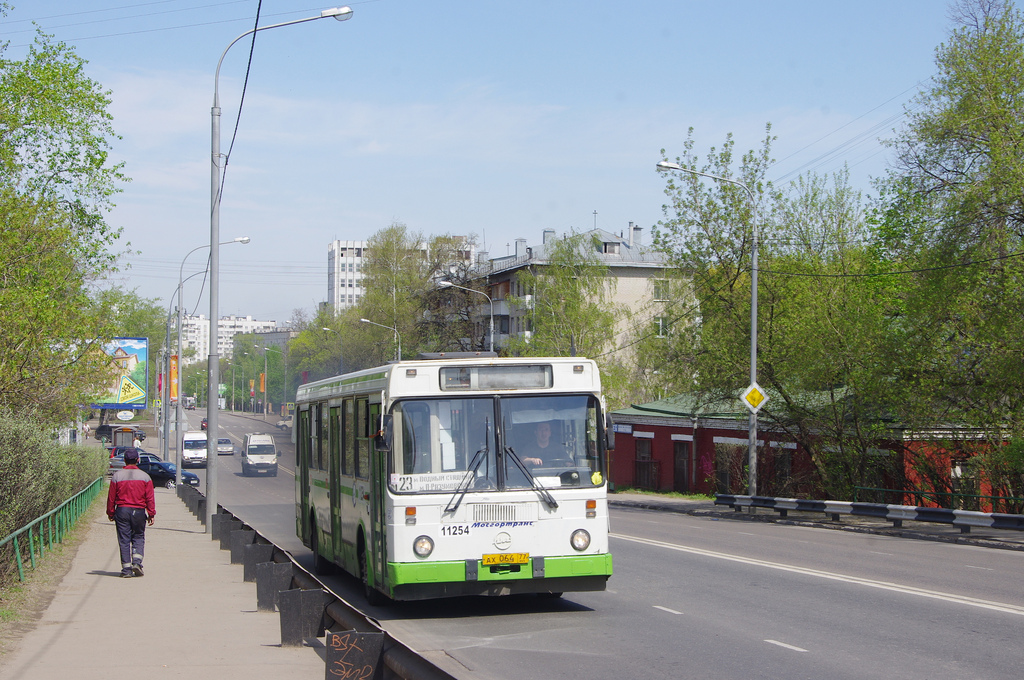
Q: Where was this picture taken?
A: On a sidewalk.